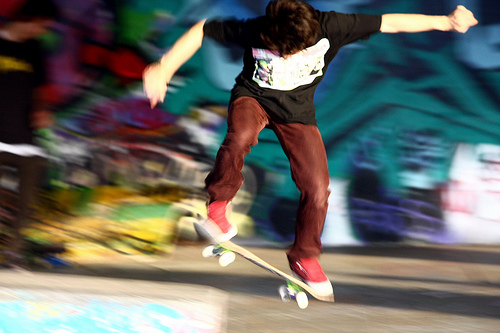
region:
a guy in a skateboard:
[181, 73, 342, 325]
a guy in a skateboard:
[168, 139, 285, 319]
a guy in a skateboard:
[233, 174, 336, 329]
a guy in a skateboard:
[189, 87, 289, 264]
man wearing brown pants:
[204, 50, 347, 310]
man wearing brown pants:
[237, 160, 298, 309]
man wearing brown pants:
[187, 84, 289, 311]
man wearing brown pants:
[188, 109, 235, 194]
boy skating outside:
[163, 11, 396, 293]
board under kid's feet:
[201, 218, 320, 300]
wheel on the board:
[213, 242, 241, 280]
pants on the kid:
[197, 138, 338, 216]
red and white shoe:
[283, 246, 335, 303]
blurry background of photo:
[355, 135, 435, 214]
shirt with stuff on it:
[220, 30, 355, 103]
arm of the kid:
[370, 6, 475, 61]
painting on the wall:
[90, 136, 136, 182]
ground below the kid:
[390, 266, 448, 328]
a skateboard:
[231, 235, 286, 327]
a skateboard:
[189, 170, 302, 329]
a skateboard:
[262, 258, 297, 326]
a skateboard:
[265, 201, 342, 318]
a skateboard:
[204, 107, 361, 306]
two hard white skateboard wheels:
[199, 241, 231, 269]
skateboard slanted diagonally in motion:
[190, 221, 336, 313]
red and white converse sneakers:
[284, 247, 340, 301]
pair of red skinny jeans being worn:
[210, 88, 338, 256]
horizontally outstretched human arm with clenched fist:
[383, 4, 479, 36]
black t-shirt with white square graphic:
[208, 11, 383, 118]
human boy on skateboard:
[133, 3, 477, 310]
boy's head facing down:
[255, 0, 321, 63]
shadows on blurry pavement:
[353, 275, 497, 323]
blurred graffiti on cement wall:
[23, 28, 134, 253]